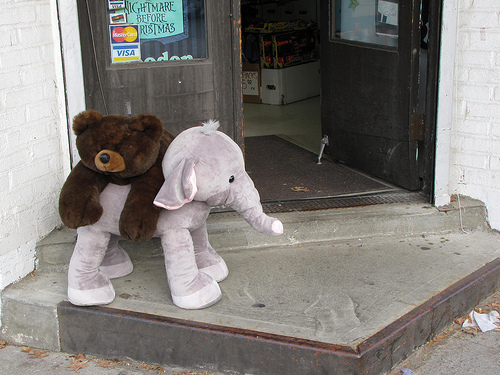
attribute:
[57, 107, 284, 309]
animals — stuffed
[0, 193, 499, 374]
steps — cement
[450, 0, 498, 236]
wall — brick, white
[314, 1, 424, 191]
door — open, old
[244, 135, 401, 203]
mat — carpet, dirty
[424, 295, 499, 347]
leaves — dead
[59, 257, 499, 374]
edge — metal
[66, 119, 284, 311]
elephant — plush, stuffed, faded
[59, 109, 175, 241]
bear — brown, plush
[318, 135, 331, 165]
door stop — metal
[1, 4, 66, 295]
brick — white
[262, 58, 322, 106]
box — white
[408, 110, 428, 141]
hinge — rusted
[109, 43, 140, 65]
sign — visa, blue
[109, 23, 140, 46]
sign — mastercard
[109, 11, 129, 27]
sign — discover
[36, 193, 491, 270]
step — diagonal